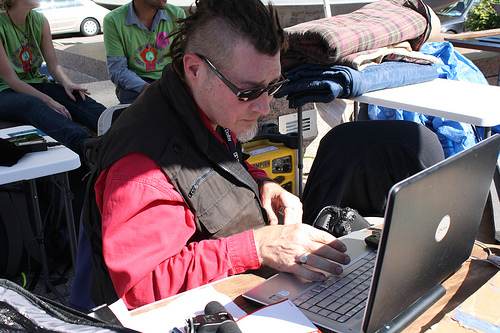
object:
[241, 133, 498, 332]
laptop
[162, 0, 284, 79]
mohawk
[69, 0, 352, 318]
man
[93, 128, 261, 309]
shirt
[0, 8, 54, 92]
tank-top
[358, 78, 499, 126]
table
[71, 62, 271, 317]
vest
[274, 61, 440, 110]
blanket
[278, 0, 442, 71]
blanket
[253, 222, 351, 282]
right-hand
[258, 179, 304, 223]
left-hand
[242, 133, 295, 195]
box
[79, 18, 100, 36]
back tire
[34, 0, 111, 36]
car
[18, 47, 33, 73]
ribbon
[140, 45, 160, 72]
ribbon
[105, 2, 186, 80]
shirt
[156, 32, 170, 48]
sticker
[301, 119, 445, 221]
jacket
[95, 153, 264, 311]
sleeve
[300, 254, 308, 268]
ring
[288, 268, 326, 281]
finger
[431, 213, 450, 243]
emblem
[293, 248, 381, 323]
keyboard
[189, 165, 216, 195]
zipper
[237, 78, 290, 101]
sunglasses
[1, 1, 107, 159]
woman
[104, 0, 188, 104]
man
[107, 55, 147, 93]
sleeve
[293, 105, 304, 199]
leg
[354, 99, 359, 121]
leg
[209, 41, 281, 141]
face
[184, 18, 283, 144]
head